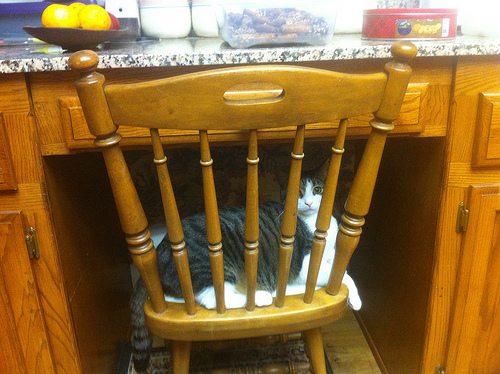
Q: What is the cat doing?
A: Sitting on chair.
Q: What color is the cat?
A: Gray and white tiger.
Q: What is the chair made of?
A: Brown wood.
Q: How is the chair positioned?
A: Its pushed up to desktop area.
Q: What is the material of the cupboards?
A: Wood.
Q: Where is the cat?
A: In the chair.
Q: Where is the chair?
A: In the kitchen.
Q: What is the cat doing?
A: Laying around.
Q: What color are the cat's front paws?
A: White.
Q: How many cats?
A: One.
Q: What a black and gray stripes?
A: The feline.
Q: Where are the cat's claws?
A: In the paws.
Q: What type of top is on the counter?
A: Marble.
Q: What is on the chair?
A: A cat.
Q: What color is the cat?
A: Black and grey stripes with solid white.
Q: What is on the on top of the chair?
A: An oval cutout.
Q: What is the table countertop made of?
A: Marble.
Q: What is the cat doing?
A: Hiding under a desk.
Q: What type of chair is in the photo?
A: A wooden spindle chair.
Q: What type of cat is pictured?
A: A grey and black striped tabby.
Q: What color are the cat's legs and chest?
A: White.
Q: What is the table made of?
A: Wood.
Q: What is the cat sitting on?
A: A chair.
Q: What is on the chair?
A: A cat.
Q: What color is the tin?
A: Red.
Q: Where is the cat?
A: Under the desk.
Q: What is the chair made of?
A: Wood.